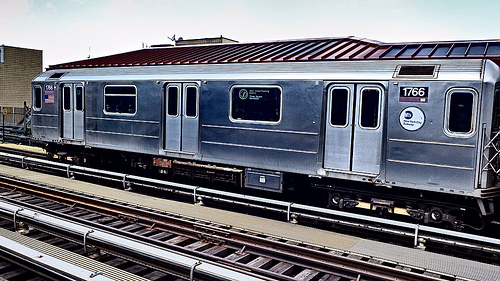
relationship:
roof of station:
[126, 19, 438, 87] [2, 25, 484, 279]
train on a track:
[16, 35, 499, 225] [1, 160, 384, 280]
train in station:
[16, 35, 499, 225] [2, 25, 484, 279]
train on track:
[16, 35, 499, 225] [11, 155, 483, 280]